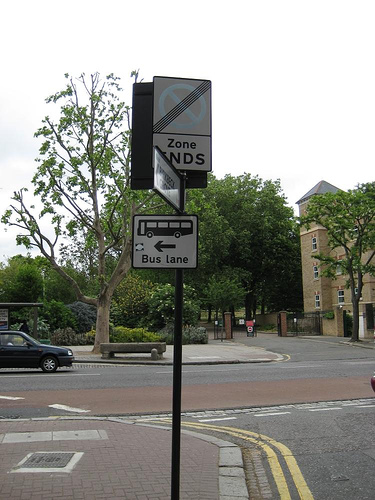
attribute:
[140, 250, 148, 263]
letter — black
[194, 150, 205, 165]
letter — black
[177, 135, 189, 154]
letter — black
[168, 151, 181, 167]
letter — black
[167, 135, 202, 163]
letter — black 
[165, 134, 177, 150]
letter — black